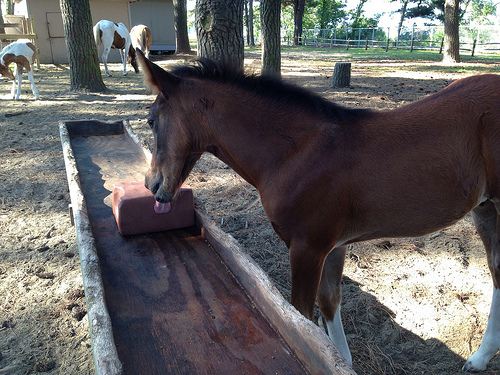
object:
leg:
[316, 246, 354, 373]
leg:
[286, 252, 320, 322]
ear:
[135, 49, 174, 94]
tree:
[331, 62, 351, 89]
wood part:
[179, 292, 209, 328]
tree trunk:
[61, 0, 105, 94]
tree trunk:
[195, 1, 243, 68]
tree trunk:
[261, 1, 282, 78]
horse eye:
[147, 116, 155, 128]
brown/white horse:
[0, 39, 40, 100]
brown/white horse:
[129, 24, 150, 59]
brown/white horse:
[93, 20, 131, 78]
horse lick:
[140, 177, 183, 217]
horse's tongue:
[152, 192, 173, 215]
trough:
[58, 112, 348, 375]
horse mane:
[167, 54, 371, 122]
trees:
[442, 0, 460, 63]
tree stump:
[333, 62, 352, 88]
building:
[26, 0, 181, 66]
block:
[112, 178, 195, 237]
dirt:
[417, 289, 456, 319]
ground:
[390, 290, 425, 330]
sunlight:
[397, 273, 449, 325]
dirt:
[381, 270, 400, 286]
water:
[225, 289, 256, 315]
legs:
[468, 207, 500, 364]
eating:
[133, 66, 140, 74]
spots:
[10, 42, 27, 63]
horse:
[130, 54, 419, 294]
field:
[13, 211, 63, 283]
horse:
[88, 18, 152, 77]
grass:
[108, 62, 146, 113]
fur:
[263, 124, 355, 202]